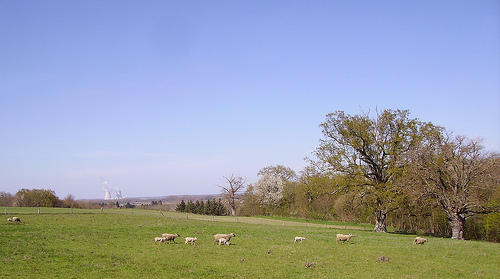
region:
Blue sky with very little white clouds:
[0, 1, 498, 199]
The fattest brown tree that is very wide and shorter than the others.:
[402, 135, 498, 238]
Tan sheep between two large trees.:
[412, 235, 428, 245]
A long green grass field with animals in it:
[3, 207, 497, 278]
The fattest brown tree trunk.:
[445, 212, 465, 239]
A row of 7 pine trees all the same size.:
[176, 199, 224, 215]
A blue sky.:
[0, 1, 499, 202]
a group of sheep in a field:
[151, 230, 433, 247]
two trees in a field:
[314, 108, 499, 240]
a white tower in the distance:
[97, 177, 125, 200]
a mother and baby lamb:
[212, 228, 237, 250]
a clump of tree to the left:
[3, 186, 58, 207]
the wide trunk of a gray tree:
[445, 203, 469, 241]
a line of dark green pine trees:
[175, 200, 229, 214]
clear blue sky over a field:
[0, 2, 498, 200]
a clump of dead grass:
[303, 262, 315, 271]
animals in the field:
[144, 205, 320, 277]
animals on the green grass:
[138, 213, 302, 275]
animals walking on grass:
[146, 226, 362, 277]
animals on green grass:
[143, 198, 261, 275]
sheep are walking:
[107, 215, 339, 276]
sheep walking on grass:
[144, 220, 304, 273]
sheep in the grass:
[150, 232, 167, 249]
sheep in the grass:
[163, 228, 182, 245]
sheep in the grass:
[183, 233, 198, 245]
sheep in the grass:
[217, 237, 228, 242]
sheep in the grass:
[213, 233, 244, 246]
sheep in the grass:
[293, 233, 310, 248]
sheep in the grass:
[334, 230, 356, 244]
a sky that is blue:
[13, 13, 390, 190]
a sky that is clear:
[26, 15, 329, 168]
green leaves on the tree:
[331, 109, 413, 183]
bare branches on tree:
[432, 167, 476, 207]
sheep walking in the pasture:
[141, 224, 256, 266]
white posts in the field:
[27, 199, 99, 217]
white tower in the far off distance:
[98, 177, 114, 204]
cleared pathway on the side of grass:
[185, 200, 380, 231]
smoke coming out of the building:
[91, 172, 128, 189]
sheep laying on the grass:
[2, 212, 30, 227]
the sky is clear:
[170, 29, 260, 101]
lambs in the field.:
[148, 227, 236, 250]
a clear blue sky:
[113, 48, 192, 98]